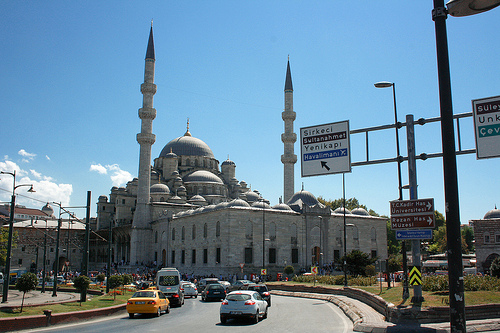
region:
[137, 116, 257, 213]
domed top of building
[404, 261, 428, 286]
neon yellow and black traffic sign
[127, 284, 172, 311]
yellow taxi cab on the road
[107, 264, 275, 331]
cars stopped at a traffic light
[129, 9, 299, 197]
two towers on a building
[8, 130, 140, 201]
clouds peeking behind buildings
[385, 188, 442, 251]
traffic signs directing traffic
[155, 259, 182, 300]
small passenger bus with break lights on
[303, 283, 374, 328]
walk way next to the treet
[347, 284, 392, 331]
brick retaining wall beside grass area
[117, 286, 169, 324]
the car is yellow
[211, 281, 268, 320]
the car is white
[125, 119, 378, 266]
the building is dome shaped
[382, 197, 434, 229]
the sign is brown in color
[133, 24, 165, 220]
the part of building is tall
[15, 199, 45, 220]
the roof is brown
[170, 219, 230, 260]
the windows are dome shaped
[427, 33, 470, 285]
the pole is black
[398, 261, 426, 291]
the sign is black and yellow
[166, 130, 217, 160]
the roof is grey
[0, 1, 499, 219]
the clouds in the small area of the clear blue sky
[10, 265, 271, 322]
the vehicles on the road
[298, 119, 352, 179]
the sign above the road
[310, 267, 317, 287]
the arrow sign on the small wall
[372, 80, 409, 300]
the street light on the grass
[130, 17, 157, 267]
the tall tower on the building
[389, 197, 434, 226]
the brown signs on the pole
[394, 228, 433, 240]
the blue sign on the pole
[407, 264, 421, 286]
the yellow and black sign on the pole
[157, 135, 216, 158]
the dome on the building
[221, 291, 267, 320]
a stalled white car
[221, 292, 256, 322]
the rear view of the white car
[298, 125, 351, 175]
a non english sign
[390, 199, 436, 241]
an illegible sign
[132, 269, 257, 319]
many cars on the street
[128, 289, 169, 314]
this car is yellow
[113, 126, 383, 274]
looks like an arab mosque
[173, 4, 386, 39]
the blue sky in the background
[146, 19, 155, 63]
the top of the tower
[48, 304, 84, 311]
some grass here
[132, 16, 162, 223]
tower on a large building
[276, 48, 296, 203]
tower on a large building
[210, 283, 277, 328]
car driving on a road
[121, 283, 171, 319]
car driving on a road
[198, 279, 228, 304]
car driving on a road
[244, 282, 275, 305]
car driving on a road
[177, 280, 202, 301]
car driving on a road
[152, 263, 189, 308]
car driving on a road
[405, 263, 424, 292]
sign on a pole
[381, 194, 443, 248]
sign on a pole